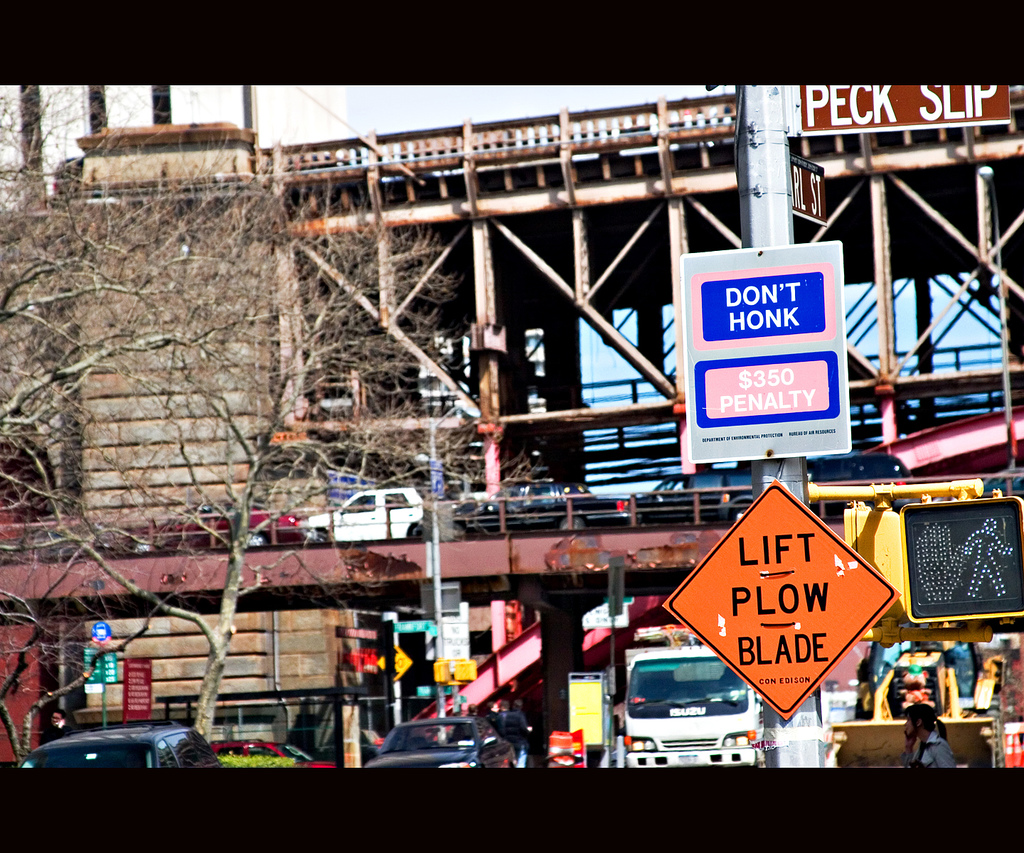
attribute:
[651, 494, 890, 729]
sign — orange, small, bright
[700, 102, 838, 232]
pole — metal, tall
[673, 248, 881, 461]
poster — blue, dark, white, pink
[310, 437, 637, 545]
cars — far, close, moving, together, crowded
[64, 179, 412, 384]
tree — bare, brown, skinny, thin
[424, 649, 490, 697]
light — yellow, close, far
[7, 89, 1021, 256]
bridge — upper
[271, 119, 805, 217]
railing — brown